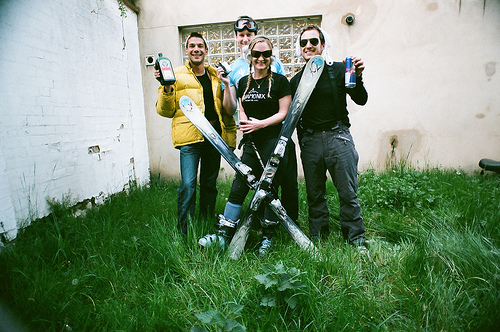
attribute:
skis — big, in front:
[178, 95, 316, 252]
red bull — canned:
[342, 56, 356, 88]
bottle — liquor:
[219, 55, 234, 74]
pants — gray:
[299, 125, 369, 246]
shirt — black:
[287, 58, 367, 136]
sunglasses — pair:
[299, 38, 325, 47]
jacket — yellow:
[154, 62, 238, 151]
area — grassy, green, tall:
[3, 169, 497, 330]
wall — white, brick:
[1, 1, 152, 239]